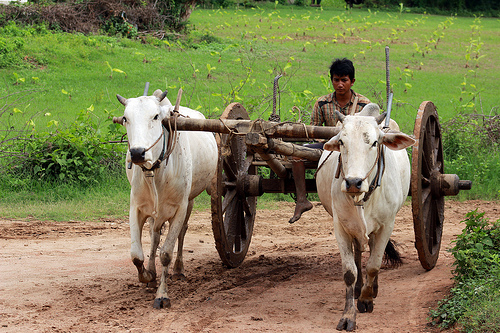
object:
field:
[0, 0, 499, 222]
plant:
[20, 126, 116, 187]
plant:
[205, 63, 217, 75]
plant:
[443, 207, 495, 279]